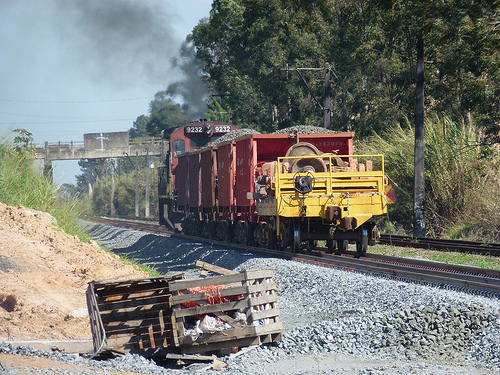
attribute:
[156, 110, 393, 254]
train — red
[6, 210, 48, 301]
hill — dirt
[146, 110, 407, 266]
train — small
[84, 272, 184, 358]
crate — empty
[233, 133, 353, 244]
train car — red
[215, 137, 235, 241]
train car — red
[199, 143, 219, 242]
train car — red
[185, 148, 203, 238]
train car — red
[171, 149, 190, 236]
train car — red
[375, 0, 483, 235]
tree — green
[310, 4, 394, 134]
tree — green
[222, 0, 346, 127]
tree — green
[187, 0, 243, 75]
tree — green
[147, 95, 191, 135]
tree — green